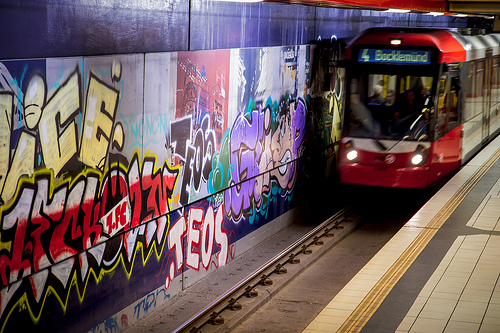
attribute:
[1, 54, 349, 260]
graffiti — purple, red, white, colorful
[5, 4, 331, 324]
wall — blue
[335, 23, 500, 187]
train — stopping, red, silver, white, coming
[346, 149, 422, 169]
headlights — lit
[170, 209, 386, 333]
track — steel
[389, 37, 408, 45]
light — overhead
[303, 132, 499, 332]
platform — tiled